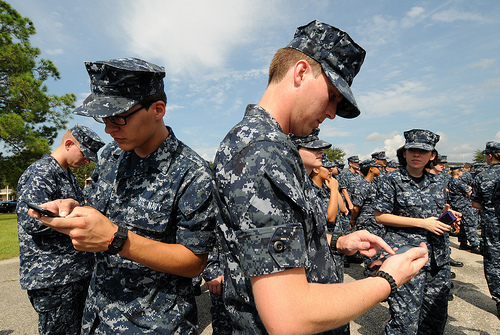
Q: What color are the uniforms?
A: Gray and blue.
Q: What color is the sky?
A: Blue.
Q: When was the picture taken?
A: Daytime.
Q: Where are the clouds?
A: In the sky.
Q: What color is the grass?
A: Green.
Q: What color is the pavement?
A: Gray.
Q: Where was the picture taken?
A: In a parking lot.